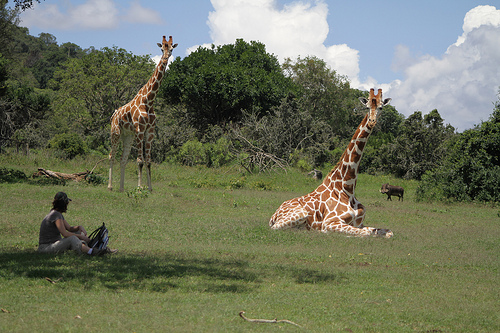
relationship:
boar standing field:
[377, 182, 407, 202] [413, 220, 465, 280]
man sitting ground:
[33, 183, 110, 253] [19, 218, 215, 305]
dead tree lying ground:
[31, 167, 99, 184] [8, 155, 497, 325]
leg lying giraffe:
[145, 125, 155, 191] [257, 97, 411, 244]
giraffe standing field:
[72, 34, 192, 195] [53, 179, 439, 331]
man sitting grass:
[36, 192, 106, 258] [118, 234, 434, 309]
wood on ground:
[27, 131, 96, 199] [156, 192, 247, 274]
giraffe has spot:
[246, 60, 408, 268] [320, 184, 337, 210]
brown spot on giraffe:
[139, 116, 146, 124] [104, 25, 181, 202]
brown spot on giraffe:
[326, 198, 337, 210] [230, 72, 437, 266]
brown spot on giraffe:
[326, 198, 337, 210] [237, 63, 426, 255]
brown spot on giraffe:
[139, 116, 146, 124] [79, 27, 191, 209]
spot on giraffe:
[357, 127, 368, 141] [266, 85, 394, 241]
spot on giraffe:
[336, 204, 347, 216] [266, 85, 394, 241]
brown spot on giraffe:
[326, 198, 337, 210] [266, 85, 394, 241]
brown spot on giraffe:
[326, 198, 337, 210] [271, 59, 407, 272]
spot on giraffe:
[333, 203, 353, 213] [266, 85, 394, 241]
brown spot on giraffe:
[139, 116, 146, 124] [108, 36, 176, 192]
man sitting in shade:
[36, 192, 106, 258] [0, 243, 340, 293]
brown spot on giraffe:
[327, 199, 336, 210] [266, 85, 394, 241]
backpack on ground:
[85, 224, 121, 259] [8, 155, 497, 325]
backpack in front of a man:
[85, 224, 121, 259] [35, 194, 87, 261]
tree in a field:
[165, 38, 285, 122] [4, 158, 499, 331]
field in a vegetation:
[4, 158, 499, 331] [2, 38, 497, 210]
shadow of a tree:
[12, 239, 358, 299] [0, 4, 55, 146]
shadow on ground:
[12, 239, 358, 299] [8, 155, 497, 325]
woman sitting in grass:
[30, 179, 115, 264] [4, 152, 496, 332]